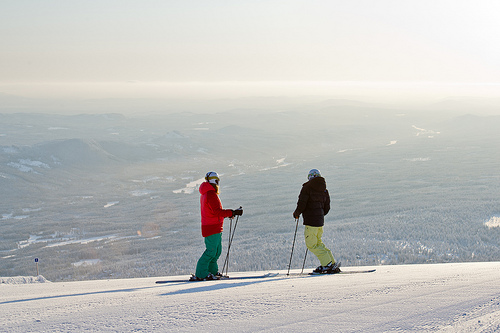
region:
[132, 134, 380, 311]
two people standing on mountain top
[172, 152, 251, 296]
a person holding ski poles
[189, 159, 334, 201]
two people wearing helmets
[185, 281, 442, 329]
tracks in the snow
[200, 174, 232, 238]
a person wearing a red coat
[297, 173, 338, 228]
a person wearing a black coat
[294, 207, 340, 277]
a person wearing yellow pants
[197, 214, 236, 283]
a person wearing green pants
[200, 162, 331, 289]
two people holding ski poles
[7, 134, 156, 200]
mountains covered with snow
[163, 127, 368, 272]
two people in the snow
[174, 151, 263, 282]
perso wearing red and blue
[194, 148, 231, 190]
head of the person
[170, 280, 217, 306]
shadow on the ground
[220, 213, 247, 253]
ski poles in hand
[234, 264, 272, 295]
skis on the ground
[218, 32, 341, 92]
sky in the distance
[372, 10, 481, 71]
light in the sky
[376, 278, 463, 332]
tracks in the snow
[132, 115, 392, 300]
two people standing in the snow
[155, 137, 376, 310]
two people standing on a mountain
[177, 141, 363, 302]
two people holding on to ski poles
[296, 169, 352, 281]
a person wearing yellow pants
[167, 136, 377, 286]
two people on snow skis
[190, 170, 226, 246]
a person wearing a red coat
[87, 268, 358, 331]
tracks in the snow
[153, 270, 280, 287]
Person on skis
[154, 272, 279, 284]
Person is on skis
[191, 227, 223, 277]
Person wearing pants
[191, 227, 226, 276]
Person is wearing pants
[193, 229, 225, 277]
Person wearing green pants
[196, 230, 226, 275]
Person is wearing green pants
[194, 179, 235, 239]
Person wearing a jacket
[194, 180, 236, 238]
Person is wearing a jacket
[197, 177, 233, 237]
Person wearing a red jacket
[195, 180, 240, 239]
Person is wearing a red jacket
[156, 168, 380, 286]
Two skiers on mountain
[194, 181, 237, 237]
Skier wearing red jacket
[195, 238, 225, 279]
Skier wearing green pants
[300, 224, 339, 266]
Skier wearing yellow pants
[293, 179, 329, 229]
Skier wearing black jacket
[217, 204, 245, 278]
Skier holding two poles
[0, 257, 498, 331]
Snow covering the ground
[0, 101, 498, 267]
Mountains in the background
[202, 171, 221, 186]
Skier wearing a hat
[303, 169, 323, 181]
Skier wearing a wool hat